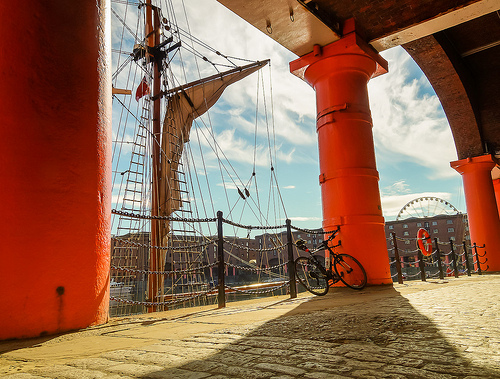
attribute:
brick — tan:
[338, 331, 408, 354]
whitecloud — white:
[371, 80, 441, 167]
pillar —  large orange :
[301, 53, 393, 285]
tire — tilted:
[332, 253, 369, 290]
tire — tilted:
[293, 253, 331, 296]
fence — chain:
[111, 205, 336, 292]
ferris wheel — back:
[396, 195, 460, 220]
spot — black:
[55, 284, 65, 298]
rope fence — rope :
[111, 208, 489, 318]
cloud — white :
[112, 2, 479, 206]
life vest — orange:
[412, 224, 437, 258]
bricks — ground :
[223, 270, 425, 377]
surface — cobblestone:
[155, 304, 489, 355]